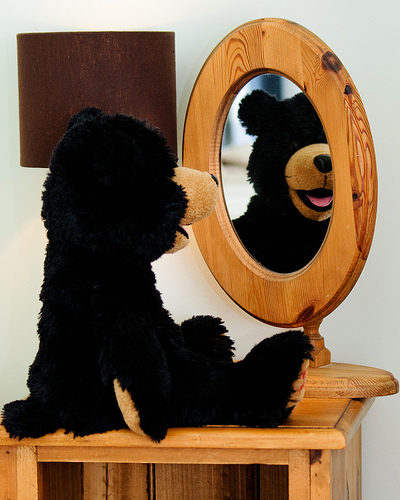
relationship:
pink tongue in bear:
[304, 193, 334, 209] [2, 104, 315, 441]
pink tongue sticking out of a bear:
[304, 193, 334, 209] [230, 90, 333, 265]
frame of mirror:
[204, 18, 327, 72] [221, 71, 333, 277]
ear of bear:
[237, 85, 277, 138] [2, 104, 315, 441]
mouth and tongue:
[290, 185, 337, 213] [302, 189, 334, 209]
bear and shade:
[2, 104, 315, 441] [17, 28, 178, 168]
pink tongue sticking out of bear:
[304, 193, 334, 209] [2, 104, 315, 441]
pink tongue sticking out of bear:
[284, 189, 334, 213] [219, 84, 355, 257]